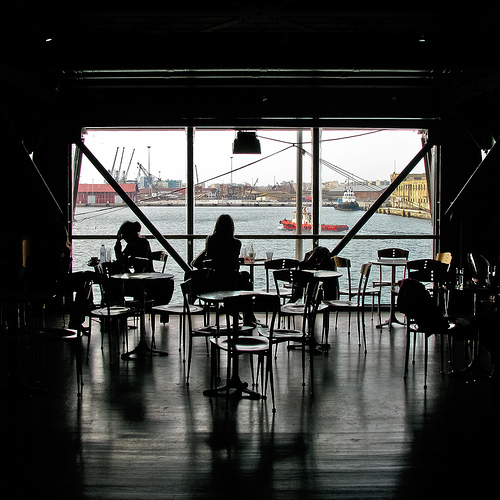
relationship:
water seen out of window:
[71, 202, 431, 303] [69, 125, 434, 305]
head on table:
[293, 248, 332, 289] [266, 258, 357, 308]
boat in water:
[276, 210, 356, 237] [76, 205, 436, 240]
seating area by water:
[76, 230, 421, 363] [199, 203, 260, 227]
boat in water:
[279, 207, 349, 231] [71, 202, 431, 303]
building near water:
[74, 173, 144, 210] [144, 213, 321, 258]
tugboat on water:
[266, 217, 374, 247] [201, 191, 333, 251]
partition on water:
[82, 196, 369, 210] [76, 199, 431, 290]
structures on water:
[117, 156, 281, 198] [223, 200, 341, 244]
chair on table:
[213, 293, 278, 414] [193, 285, 271, 405]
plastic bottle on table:
[97, 242, 109, 264] [85, 261, 170, 271]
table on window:
[369, 257, 410, 327] [69, 125, 434, 305]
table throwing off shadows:
[198, 288, 267, 400] [209, 395, 307, 493]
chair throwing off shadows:
[180, 276, 253, 398] [209, 395, 307, 493]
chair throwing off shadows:
[205, 291, 282, 415] [209, 395, 307, 493]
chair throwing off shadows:
[258, 274, 323, 388] [209, 395, 307, 493]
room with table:
[30, 97, 498, 469] [193, 285, 280, 405]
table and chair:
[193, 285, 280, 405] [257, 290, 336, 365]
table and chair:
[193, 285, 280, 405] [168, 279, 213, 351]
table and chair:
[193, 285, 280, 405] [213, 286, 309, 377]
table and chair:
[193, 285, 271, 405] [216, 287, 282, 411]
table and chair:
[193, 285, 271, 405] [176, 273, 236, 391]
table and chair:
[9, 261, 54, 319] [49, 266, 90, 366]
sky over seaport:
[175, 162, 225, 192] [83, 177, 470, 344]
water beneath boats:
[175, 198, 189, 248] [276, 214, 314, 235]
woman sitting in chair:
[188, 191, 244, 295] [175, 255, 199, 292]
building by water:
[381, 167, 430, 212] [164, 196, 176, 246]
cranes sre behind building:
[113, 152, 135, 174] [75, 182, 148, 212]